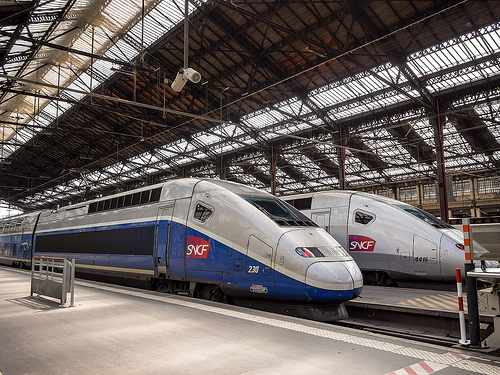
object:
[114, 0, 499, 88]
background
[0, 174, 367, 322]
train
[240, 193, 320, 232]
windshield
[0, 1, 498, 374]
station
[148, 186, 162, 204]
window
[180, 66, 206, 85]
light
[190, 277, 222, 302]
wheel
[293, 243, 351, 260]
light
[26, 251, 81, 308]
equipment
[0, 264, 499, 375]
platform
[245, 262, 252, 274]
numbers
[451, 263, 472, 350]
marker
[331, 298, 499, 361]
track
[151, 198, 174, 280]
door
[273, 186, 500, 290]
train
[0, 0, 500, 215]
roof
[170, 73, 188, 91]
loudspeakers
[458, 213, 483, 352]
rail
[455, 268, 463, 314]
stripes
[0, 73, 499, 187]
beam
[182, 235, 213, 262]
sign